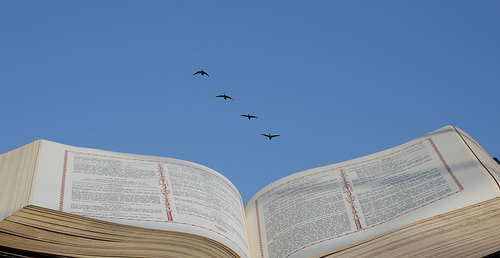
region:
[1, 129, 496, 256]
This is an open book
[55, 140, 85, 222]
Red border on pages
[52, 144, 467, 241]
Red borders on book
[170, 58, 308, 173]
Four birds in the sky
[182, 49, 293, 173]
Birds are flying in the sky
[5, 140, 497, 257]
Off white book pages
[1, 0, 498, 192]
Clear and sunny blue skies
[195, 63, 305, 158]
Silhouette of birds flying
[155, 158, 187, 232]
Detailed border on page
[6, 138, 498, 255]
Large book being read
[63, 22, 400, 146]
four birds in a blue sky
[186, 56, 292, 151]
four black birds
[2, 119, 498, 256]
the book is open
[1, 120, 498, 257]
the leaves of the book are white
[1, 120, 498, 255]
red lines in a book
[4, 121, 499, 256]
the book is fat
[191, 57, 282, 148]
birds flying in line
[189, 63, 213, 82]
bird first in line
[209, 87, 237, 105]
bird second in line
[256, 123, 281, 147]
bird last in line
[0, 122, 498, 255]
A big and thick open book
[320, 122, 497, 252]
Several pages on one side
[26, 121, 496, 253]
The page that is open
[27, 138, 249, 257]
One open page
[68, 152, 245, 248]
The printed matter on one page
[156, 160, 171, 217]
A red marking making two columns of the printed matter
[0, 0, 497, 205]
Cloudless blue sky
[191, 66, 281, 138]
Four birds flying in the sky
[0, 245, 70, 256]
Black thick binding cover of the book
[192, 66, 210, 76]
The bird in front of the row of flying birds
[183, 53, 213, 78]
Large bird flying in sky.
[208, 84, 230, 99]
Large bird flying in sky.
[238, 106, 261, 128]
Large bird flying in sky.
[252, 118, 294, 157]
Large bird flying in sky.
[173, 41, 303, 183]
4 birds flying in sky.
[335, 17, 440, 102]
Sky is blue in color.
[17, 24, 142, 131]
Sky is blue and clear.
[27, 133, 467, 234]
Large book is open.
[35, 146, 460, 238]
Pages of book are white.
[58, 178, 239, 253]
Book has many pages.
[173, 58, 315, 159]
a objects in air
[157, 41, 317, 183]
few objects flying in air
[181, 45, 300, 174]
birds flying in air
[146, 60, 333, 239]
a beautiful view of birds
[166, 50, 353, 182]
a superb angle of birds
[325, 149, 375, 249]
a red line in book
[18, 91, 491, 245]
a book placed on top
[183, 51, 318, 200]
four birds in air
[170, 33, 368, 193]
birds flying in design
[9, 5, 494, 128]
a beautiful view of sky